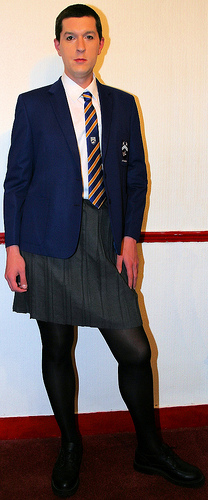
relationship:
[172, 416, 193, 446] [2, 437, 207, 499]
carpet on floor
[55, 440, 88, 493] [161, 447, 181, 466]
shoe has lace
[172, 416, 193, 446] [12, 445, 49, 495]
carpet on floor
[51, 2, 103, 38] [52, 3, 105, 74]
hair on head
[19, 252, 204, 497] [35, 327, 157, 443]
legs in nylons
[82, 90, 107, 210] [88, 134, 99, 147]
tie has emblem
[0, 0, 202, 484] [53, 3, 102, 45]
man has hair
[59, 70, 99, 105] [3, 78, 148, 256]
collar under jacket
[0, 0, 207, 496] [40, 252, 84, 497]
person has legs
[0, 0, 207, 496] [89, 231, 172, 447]
person has leg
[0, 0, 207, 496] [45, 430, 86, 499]
person has shoe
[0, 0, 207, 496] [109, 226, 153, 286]
person has hand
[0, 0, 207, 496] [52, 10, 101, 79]
person has face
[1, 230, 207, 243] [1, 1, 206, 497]
wood on wall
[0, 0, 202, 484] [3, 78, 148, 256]
man wearing jacket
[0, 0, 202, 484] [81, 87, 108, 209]
man wearing tie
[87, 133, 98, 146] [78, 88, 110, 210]
logo on tie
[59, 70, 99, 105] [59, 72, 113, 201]
collar has shirt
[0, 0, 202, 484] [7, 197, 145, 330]
man wearing skirt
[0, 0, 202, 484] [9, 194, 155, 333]
man in pleated skirt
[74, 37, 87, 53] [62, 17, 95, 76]
nose on face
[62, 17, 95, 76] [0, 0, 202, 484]
face of man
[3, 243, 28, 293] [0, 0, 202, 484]
right hand of man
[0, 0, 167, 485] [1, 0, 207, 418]
man standing against wall